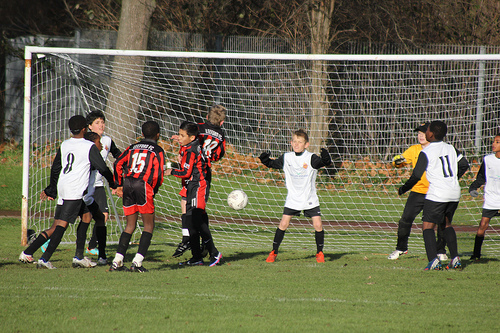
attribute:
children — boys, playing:
[13, 102, 496, 276]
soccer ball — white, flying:
[220, 174, 256, 217]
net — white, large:
[21, 54, 487, 273]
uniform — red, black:
[122, 138, 153, 269]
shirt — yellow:
[390, 151, 435, 193]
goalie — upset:
[397, 117, 458, 256]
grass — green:
[13, 168, 494, 319]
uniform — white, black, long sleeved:
[30, 107, 116, 274]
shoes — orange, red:
[255, 245, 337, 289]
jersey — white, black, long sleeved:
[40, 139, 110, 207]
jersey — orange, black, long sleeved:
[110, 142, 169, 194]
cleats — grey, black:
[26, 258, 102, 278]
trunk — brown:
[114, 9, 171, 187]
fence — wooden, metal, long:
[5, 39, 495, 163]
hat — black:
[396, 126, 433, 156]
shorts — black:
[269, 210, 326, 226]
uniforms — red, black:
[103, 114, 235, 250]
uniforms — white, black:
[48, 132, 130, 272]